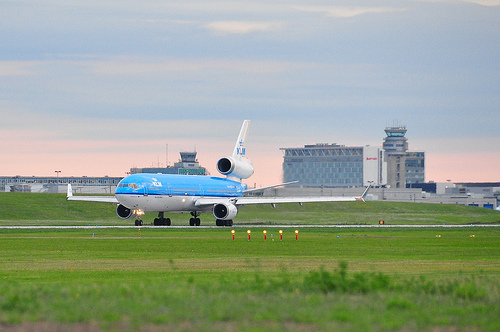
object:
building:
[279, 118, 425, 188]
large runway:
[0, 224, 497, 228]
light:
[294, 230, 299, 241]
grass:
[0, 192, 499, 331]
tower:
[382, 119, 408, 188]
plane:
[66, 119, 300, 225]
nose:
[114, 173, 144, 209]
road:
[0, 192, 499, 332]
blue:
[115, 173, 246, 197]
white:
[66, 183, 378, 220]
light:
[279, 229, 284, 240]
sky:
[0, 0, 500, 183]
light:
[231, 229, 236, 241]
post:
[295, 229, 299, 240]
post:
[279, 229, 283, 240]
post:
[263, 229, 268, 240]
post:
[246, 229, 251, 241]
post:
[231, 229, 236, 241]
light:
[262, 230, 267, 241]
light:
[247, 230, 252, 242]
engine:
[212, 201, 237, 220]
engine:
[115, 204, 137, 220]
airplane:
[58, 110, 303, 230]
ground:
[0, 192, 499, 331]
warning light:
[262, 230, 267, 241]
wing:
[235, 185, 379, 209]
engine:
[216, 156, 254, 179]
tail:
[216, 119, 254, 179]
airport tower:
[383, 119, 409, 188]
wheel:
[215, 219, 233, 226]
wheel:
[189, 218, 200, 226]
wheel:
[154, 218, 172, 226]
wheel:
[135, 219, 143, 225]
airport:
[0, 177, 500, 332]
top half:
[115, 173, 247, 197]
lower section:
[0, 120, 497, 190]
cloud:
[0, 0, 499, 184]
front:
[115, 173, 147, 212]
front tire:
[135, 219, 144, 226]